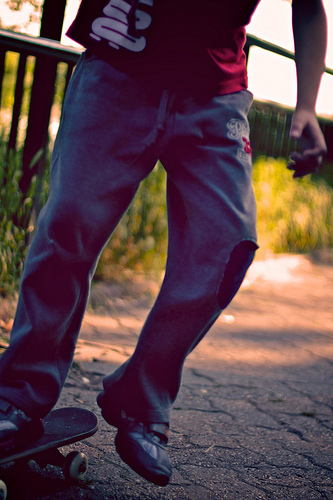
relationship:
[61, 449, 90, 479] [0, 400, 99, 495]
wheels on black skateboard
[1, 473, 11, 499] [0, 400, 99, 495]
wheels on black skateboard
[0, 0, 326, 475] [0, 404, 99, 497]
person on skateboard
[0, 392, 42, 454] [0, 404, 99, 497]
foot on skateboard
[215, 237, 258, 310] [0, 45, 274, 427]
patch on sweatpants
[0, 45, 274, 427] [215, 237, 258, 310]
sweatpants with patch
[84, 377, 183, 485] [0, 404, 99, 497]
foot off skateboard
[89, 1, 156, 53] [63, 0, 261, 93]
text on red shirt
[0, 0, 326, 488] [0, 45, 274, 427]
person wearing sweatpants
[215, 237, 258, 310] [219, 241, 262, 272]
patch on knee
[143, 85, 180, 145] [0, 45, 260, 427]
drawstring on sweatpants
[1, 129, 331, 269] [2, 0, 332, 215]
tall grass next to fence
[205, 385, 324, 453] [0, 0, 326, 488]
pavement beneath person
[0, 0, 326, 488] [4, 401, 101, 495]
person has a skateboard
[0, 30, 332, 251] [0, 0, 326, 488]
fence behind person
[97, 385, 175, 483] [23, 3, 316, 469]
black shoe on a person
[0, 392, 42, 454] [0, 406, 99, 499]
foot on a black skateboard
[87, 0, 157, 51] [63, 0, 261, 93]
logo on red shirt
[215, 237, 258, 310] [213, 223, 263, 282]
patch on knee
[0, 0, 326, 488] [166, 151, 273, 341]
person has leg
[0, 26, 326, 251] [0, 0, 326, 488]
fence behind person